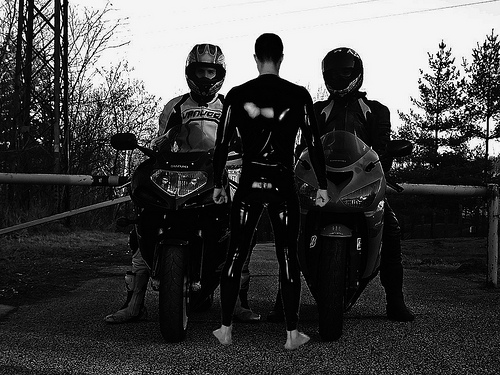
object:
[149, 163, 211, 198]
lights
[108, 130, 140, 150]
mirror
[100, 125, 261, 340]
motorcycle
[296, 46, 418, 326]
person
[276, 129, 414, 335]
motorcycle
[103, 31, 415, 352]
people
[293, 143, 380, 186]
windshield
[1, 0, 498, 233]
trees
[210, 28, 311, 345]
clock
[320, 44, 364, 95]
motorcycle helmet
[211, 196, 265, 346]
leg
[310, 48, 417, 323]
man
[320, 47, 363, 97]
helmet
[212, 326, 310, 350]
bare feet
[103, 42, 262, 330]
person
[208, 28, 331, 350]
person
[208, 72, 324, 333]
bodysuit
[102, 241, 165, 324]
boots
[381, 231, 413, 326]
boots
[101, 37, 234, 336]
rider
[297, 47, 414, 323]
rider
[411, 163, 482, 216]
ground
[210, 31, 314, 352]
man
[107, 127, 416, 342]
bikes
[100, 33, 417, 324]
two men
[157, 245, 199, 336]
tire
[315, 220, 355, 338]
tire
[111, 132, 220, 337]
bike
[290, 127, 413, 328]
bike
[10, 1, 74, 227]
electrical pole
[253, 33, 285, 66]
head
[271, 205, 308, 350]
leg